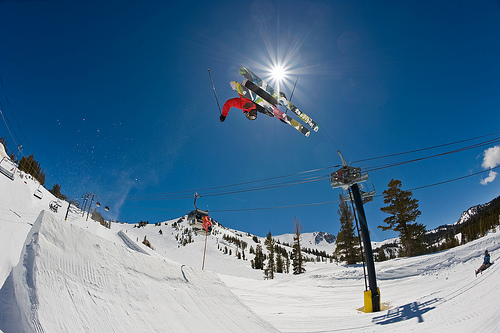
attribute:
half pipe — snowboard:
[13, 205, 278, 331]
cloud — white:
[62, 89, 211, 221]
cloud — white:
[482, 141, 498, 186]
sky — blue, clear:
[0, 0, 499, 241]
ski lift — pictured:
[75, 130, 499, 311]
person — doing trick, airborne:
[214, 72, 284, 127]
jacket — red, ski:
[218, 96, 260, 119]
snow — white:
[68, 259, 256, 323]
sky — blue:
[12, 5, 498, 226]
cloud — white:
[56, 157, 156, 224]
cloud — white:
[477, 141, 497, 191]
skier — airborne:
[185, 62, 307, 138]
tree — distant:
[381, 178, 427, 256]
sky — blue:
[2, 17, 489, 222]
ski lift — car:
[315, 159, 395, 214]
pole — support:
[336, 156, 386, 313]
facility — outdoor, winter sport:
[11, 176, 321, 329]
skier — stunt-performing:
[175, 65, 335, 155]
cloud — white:
[81, 160, 140, 218]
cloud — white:
[475, 142, 485, 173]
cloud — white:
[474, 170, 484, 188]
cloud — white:
[475, 142, 484, 170]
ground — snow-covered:
[0, 144, 498, 331]